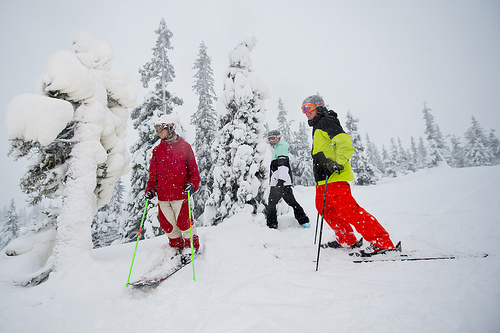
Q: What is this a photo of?
A: Skiers.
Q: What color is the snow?
A: White.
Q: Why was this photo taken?
A: To show skiers.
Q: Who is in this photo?
A: Three skiers.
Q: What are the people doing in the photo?
A: Skiing.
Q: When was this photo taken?
A: In the daytime.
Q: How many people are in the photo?
A: Three.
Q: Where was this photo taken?
A: On a ski mountain.